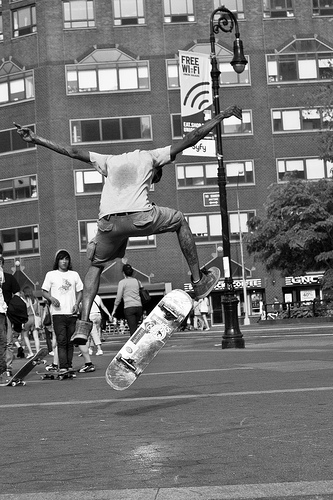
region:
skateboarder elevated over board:
[7, 101, 271, 392]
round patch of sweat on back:
[85, 140, 168, 214]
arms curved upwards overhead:
[7, 99, 243, 168]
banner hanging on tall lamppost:
[171, 2, 240, 344]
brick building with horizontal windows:
[0, 40, 326, 244]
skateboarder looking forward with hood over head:
[32, 241, 80, 376]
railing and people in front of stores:
[182, 270, 324, 323]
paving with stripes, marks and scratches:
[1, 329, 324, 492]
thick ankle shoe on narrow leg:
[65, 260, 100, 342]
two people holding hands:
[90, 262, 145, 356]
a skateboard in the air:
[104, 287, 193, 395]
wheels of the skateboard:
[156, 298, 185, 324]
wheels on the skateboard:
[113, 351, 142, 378]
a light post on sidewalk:
[205, 2, 249, 351]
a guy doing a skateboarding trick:
[10, 101, 244, 392]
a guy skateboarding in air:
[11, 102, 245, 392]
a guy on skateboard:
[32, 247, 86, 381]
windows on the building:
[172, 157, 256, 191]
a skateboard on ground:
[0, 346, 51, 391]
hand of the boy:
[165, 109, 256, 169]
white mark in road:
[122, 433, 162, 456]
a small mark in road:
[110, 429, 206, 488]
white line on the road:
[161, 374, 328, 410]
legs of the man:
[65, 264, 106, 358]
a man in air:
[64, 277, 222, 303]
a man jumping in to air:
[52, 123, 247, 370]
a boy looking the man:
[34, 240, 77, 306]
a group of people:
[18, 251, 257, 378]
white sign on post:
[178, 48, 216, 139]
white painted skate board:
[103, 290, 191, 387]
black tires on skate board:
[116, 354, 142, 377]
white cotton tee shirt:
[88, 145, 172, 214]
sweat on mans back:
[111, 163, 139, 191]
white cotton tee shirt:
[40, 270, 84, 315]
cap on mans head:
[52, 246, 71, 261]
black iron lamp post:
[208, 6, 247, 349]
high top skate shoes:
[190, 267, 221, 300]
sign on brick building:
[201, 192, 219, 208]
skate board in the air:
[102, 268, 214, 400]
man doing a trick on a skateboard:
[21, 134, 248, 391]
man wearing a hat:
[49, 248, 71, 264]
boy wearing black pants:
[53, 310, 76, 358]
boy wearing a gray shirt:
[89, 146, 159, 211]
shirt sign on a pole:
[198, 188, 226, 213]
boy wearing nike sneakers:
[183, 258, 224, 295]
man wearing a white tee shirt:
[32, 265, 89, 312]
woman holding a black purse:
[131, 278, 151, 310]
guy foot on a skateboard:
[47, 360, 72, 378]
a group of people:
[5, 243, 100, 395]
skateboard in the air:
[83, 277, 217, 404]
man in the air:
[5, 95, 257, 357]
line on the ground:
[2, 378, 330, 411]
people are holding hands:
[88, 291, 131, 343]